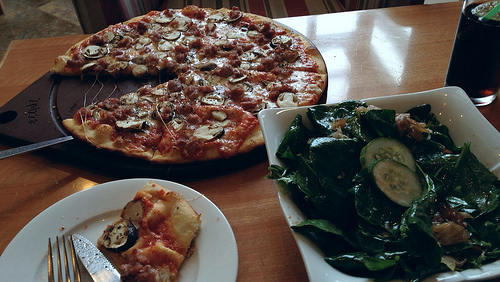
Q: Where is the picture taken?
A: Restaurant.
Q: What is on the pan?
A: Pizza.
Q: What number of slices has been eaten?
A: One.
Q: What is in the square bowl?
A: Spinach and cucumbers.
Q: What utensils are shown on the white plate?
A: Fork and a knife.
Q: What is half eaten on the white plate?
A: Piece of pizza.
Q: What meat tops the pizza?
A: Sausage.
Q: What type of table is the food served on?
A: Formica.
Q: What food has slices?
A: Pizza.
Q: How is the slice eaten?
A: Knife and fork.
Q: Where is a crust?
A: Edge of pizza.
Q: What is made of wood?
A: Table.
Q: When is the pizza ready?
A: Now.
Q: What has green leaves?
A: Salad.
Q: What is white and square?
A: Salad plate.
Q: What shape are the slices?
A: Triangles.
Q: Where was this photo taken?
A: In a restaurant.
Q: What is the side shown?
A: Salad.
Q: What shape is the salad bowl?
A: Square.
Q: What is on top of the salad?
A: Cucumbers.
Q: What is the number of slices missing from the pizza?
A: One.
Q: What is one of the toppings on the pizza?
A: Mushrooms.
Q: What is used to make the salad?
A: Spinach.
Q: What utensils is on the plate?
A: Knife and fork.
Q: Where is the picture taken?
A: A restaurant.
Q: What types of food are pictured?
A: Pizza and salad.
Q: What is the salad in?
A: A bowl.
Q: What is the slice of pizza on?
A: A plate.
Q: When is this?
A: Lunchtime.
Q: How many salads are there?
A: One.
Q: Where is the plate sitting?
A: On the table.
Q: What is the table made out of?
A: Wood.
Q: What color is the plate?
A: White.